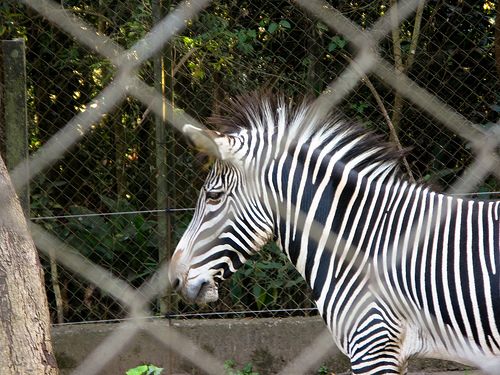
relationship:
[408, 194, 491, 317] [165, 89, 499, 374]
black stripe on zebra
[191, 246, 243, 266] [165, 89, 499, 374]
stripe on zebra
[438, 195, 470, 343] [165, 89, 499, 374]
black stripe on zebra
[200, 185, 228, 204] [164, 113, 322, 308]
eye on head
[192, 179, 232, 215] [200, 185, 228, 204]
zebra has eye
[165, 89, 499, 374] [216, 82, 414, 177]
zebra has mane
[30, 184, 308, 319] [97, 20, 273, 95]
bush has leaves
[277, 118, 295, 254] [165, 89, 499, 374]
black stripe on zebra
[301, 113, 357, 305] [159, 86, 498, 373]
black stripe on zebra